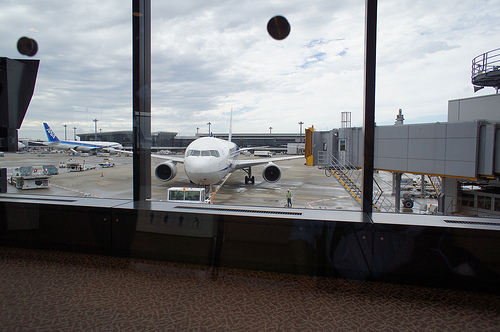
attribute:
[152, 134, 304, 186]
jet — white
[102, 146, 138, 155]
wing — blue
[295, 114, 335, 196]
door — yellow, bown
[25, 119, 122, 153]
plane — white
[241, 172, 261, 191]
wheel —  right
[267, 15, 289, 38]
circle — black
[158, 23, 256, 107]
clouds — these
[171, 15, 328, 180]
glass — large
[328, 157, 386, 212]
steps — yellow, gray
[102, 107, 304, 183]
white plane — large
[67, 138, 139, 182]
truck — white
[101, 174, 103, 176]
cone — orange, traffic cone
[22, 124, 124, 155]
plane — white, blue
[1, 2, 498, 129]
sky — blue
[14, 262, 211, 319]
carpet — brown, black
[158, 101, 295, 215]
plane — big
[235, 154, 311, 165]
wing — large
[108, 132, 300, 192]
plane — white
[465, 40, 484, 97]
balcony — tall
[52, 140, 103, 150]
stripe — blue